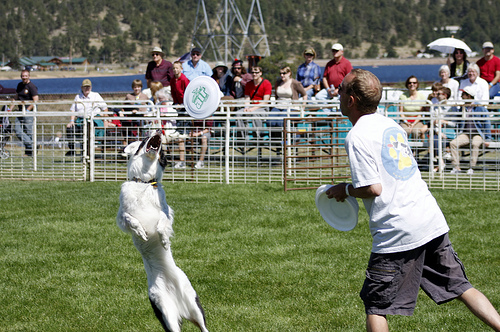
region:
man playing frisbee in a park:
[315, 68, 499, 329]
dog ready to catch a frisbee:
[118, 128, 208, 330]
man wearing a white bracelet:
[343, 182, 352, 196]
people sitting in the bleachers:
[17, 37, 497, 173]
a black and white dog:
[113, 130, 208, 328]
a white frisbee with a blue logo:
[181, 78, 219, 119]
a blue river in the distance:
[0, 61, 440, 91]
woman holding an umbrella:
[427, 33, 474, 80]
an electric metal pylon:
[191, 3, 271, 60]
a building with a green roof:
[20, 55, 85, 71]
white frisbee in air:
[176, 80, 228, 127]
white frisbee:
[183, 72, 221, 119]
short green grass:
[247, 223, 286, 256]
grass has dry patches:
[43, 205, 73, 230]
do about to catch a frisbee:
[107, 80, 253, 330]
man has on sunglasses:
[316, 70, 406, 117]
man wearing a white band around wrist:
[342, 153, 354, 208]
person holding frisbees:
[301, 58, 447, 235]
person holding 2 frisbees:
[310, 61, 418, 228]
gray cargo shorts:
[360, 217, 477, 320]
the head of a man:
[328, 63, 390, 130]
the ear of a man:
[327, 89, 362, 116]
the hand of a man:
[317, 166, 361, 220]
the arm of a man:
[337, 140, 412, 205]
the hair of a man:
[331, 53, 401, 117]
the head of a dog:
[123, 117, 185, 183]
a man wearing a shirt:
[319, 74, 469, 264]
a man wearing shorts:
[354, 163, 490, 319]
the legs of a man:
[111, 197, 202, 279]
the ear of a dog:
[108, 114, 151, 170]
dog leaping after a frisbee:
[111, 73, 243, 331]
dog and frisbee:
[109, 75, 240, 331]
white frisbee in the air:
[181, 75, 223, 122]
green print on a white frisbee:
[184, 81, 211, 110]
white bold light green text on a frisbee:
[183, 86, 214, 109]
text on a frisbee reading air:
[191, 81, 212, 111]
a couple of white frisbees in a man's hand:
[311, 179, 361, 231]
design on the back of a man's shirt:
[378, 124, 420, 179]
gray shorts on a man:
[356, 233, 476, 319]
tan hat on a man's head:
[79, 77, 96, 87]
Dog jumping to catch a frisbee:
[108, 73, 223, 330]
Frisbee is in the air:
[181, 72, 224, 119]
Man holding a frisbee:
[311, 181, 365, 235]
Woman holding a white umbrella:
[427, 29, 474, 58]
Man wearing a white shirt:
[339, 112, 453, 255]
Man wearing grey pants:
[358, 229, 475, 314]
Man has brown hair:
[339, 66, 385, 113]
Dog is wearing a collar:
[122, 176, 161, 186]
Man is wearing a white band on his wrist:
[343, 184, 351, 199]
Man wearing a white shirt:
[68, 89, 108, 118]